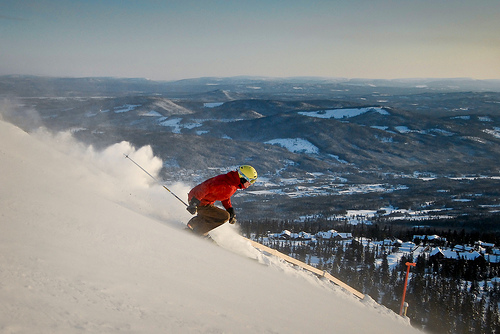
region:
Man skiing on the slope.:
[120, 148, 260, 250]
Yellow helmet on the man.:
[232, 159, 259, 191]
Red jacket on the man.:
[186, 161, 257, 221]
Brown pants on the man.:
[181, 158, 260, 241]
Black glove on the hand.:
[182, 195, 204, 216]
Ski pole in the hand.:
[118, 148, 202, 218]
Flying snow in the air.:
[78, 129, 190, 216]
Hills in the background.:
[6, 75, 494, 166]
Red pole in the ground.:
[393, 252, 418, 320]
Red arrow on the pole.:
[400, 256, 420, 269]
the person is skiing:
[118, 131, 256, 243]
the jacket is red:
[185, 168, 240, 208]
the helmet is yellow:
[237, 165, 259, 182]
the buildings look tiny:
[267, 226, 389, 245]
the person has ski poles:
[121, 147, 256, 239]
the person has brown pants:
[193, 202, 228, 239]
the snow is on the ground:
[1, 243, 295, 333]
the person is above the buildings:
[8, 78, 490, 275]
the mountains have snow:
[231, 95, 416, 160]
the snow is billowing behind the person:
[32, 122, 259, 255]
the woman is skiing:
[125, 119, 305, 286]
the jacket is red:
[169, 159, 275, 230]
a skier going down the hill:
[10, 90, 420, 320]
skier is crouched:
[183, 148, 259, 236]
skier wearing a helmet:
[177, 155, 257, 227]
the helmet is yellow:
[226, 153, 268, 198]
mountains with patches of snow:
[85, 51, 491, 161]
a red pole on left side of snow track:
[385, 252, 426, 310]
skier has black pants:
[182, 157, 257, 237]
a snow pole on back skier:
[120, 131, 185, 206]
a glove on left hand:
[225, 201, 240, 226]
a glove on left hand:
[219, 203, 249, 227]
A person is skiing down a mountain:
[10, 8, 471, 315]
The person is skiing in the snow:
[5, 30, 465, 325]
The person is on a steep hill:
[5, 25, 471, 330]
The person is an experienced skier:
[10, 25, 475, 325]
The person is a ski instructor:
[6, 25, 476, 330]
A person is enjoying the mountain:
[6, 25, 477, 326]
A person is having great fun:
[7, 26, 482, 313]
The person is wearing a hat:
[20, 31, 471, 312]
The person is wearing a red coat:
[5, 32, 482, 312]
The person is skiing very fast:
[6, 35, 483, 320]